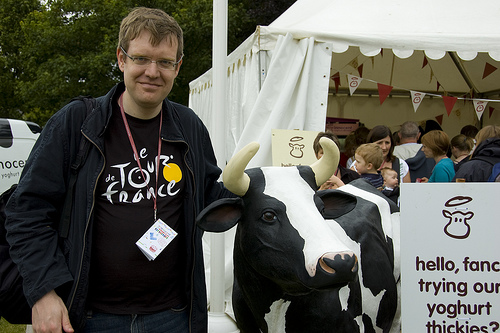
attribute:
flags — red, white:
[329, 67, 499, 131]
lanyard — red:
[115, 85, 170, 225]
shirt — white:
[78, 105, 205, 321]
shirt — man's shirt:
[83, 94, 190, 312]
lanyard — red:
[116, 110, 183, 212]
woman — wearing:
[414, 130, 462, 185]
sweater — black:
[48, 97, 236, 330]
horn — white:
[217, 139, 262, 199]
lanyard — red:
[113, 90, 166, 221]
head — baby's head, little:
[418, 195, 475, 254]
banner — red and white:
[335, 67, 499, 118]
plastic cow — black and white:
[217, 130, 406, 325]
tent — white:
[189, 0, 499, 330]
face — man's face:
[115, 31, 180, 103]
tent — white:
[187, 1, 499, 168]